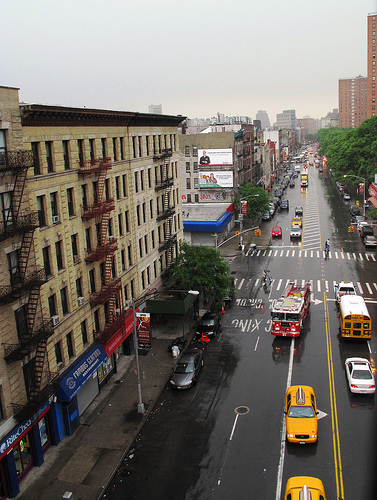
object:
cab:
[283, 380, 320, 449]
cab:
[281, 472, 337, 498]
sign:
[293, 382, 309, 405]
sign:
[299, 483, 313, 500]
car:
[341, 355, 377, 396]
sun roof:
[350, 358, 368, 366]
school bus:
[336, 292, 373, 345]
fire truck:
[269, 281, 311, 340]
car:
[169, 338, 204, 390]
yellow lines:
[322, 288, 340, 500]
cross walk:
[233, 277, 376, 294]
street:
[266, 174, 375, 473]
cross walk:
[245, 242, 376, 263]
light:
[188, 288, 201, 301]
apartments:
[18, 103, 186, 409]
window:
[45, 135, 59, 175]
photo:
[6, 7, 377, 496]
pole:
[127, 303, 148, 418]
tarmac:
[149, 409, 206, 500]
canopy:
[145, 285, 197, 345]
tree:
[334, 121, 375, 188]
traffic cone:
[220, 303, 226, 314]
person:
[321, 238, 332, 259]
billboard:
[198, 148, 234, 166]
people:
[198, 150, 212, 170]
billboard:
[193, 167, 236, 191]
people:
[198, 172, 219, 191]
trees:
[234, 178, 268, 225]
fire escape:
[2, 145, 54, 421]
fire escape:
[77, 155, 129, 339]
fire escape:
[148, 141, 185, 280]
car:
[270, 223, 284, 242]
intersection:
[247, 235, 376, 293]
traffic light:
[251, 226, 262, 237]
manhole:
[233, 401, 252, 415]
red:
[257, 231, 259, 233]